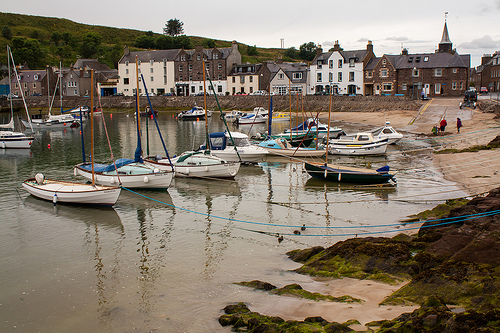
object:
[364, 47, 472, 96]
buildings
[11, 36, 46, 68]
tree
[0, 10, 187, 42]
hill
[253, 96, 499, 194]
shoreline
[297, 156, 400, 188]
boat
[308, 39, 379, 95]
building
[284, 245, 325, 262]
rock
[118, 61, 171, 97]
wall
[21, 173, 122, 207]
white boat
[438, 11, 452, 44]
steeple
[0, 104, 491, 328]
water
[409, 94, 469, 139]
ramp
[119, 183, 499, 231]
rope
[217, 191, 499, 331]
shore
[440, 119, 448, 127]
red coat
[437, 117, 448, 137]
person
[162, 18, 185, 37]
tree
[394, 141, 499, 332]
beach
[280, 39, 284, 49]
ledge